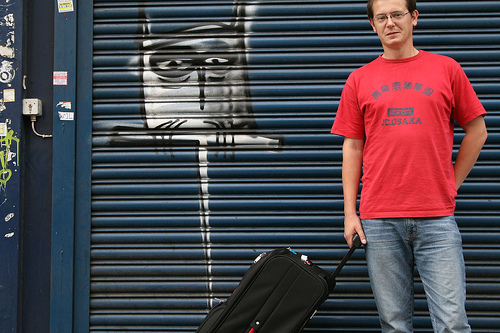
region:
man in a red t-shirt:
[335, 3, 486, 331]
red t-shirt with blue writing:
[330, 53, 484, 211]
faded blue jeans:
[360, 220, 466, 332]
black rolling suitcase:
[180, 233, 362, 330]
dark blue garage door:
[85, 3, 497, 328]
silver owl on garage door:
[112, 5, 281, 318]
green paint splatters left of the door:
[0, 115, 20, 185]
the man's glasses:
[376, 9, 411, 19]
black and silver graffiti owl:
[112, 4, 284, 305]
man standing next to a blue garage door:
[332, 0, 487, 331]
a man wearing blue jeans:
[358, 234, 468, 329]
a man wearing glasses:
[350, 9, 419, 44]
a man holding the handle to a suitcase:
[306, 97, 376, 303]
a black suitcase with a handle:
[226, 220, 368, 330]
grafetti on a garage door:
[113, 6, 288, 166]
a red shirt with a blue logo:
[363, 67, 442, 149]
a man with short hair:
[358, 0, 423, 38]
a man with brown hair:
[349, 2, 441, 39]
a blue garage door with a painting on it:
[106, 19, 347, 239]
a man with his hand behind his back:
[422, 91, 486, 248]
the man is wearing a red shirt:
[333, 46, 483, 216]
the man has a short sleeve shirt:
[330, 48, 485, 216]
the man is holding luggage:
[197, 237, 364, 332]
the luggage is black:
[198, 230, 362, 328]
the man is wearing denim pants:
[358, 220, 475, 330]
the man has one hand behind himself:
[447, 117, 485, 201]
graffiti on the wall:
[116, 4, 273, 311]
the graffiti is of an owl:
[112, 3, 277, 318]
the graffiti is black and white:
[111, 0, 277, 307]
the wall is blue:
[1, 0, 496, 330]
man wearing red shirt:
[346, 5, 496, 329]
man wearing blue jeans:
[350, 5, 488, 328]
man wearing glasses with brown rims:
[363, 1, 437, 53]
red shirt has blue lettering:
[337, 65, 470, 218]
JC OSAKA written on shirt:
[376, 113, 433, 129]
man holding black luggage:
[208, 223, 363, 331]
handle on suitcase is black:
[326, 220, 365, 303]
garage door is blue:
[59, 7, 496, 330]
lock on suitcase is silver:
[296, 250, 316, 274]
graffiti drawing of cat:
[106, 10, 316, 317]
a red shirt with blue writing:
[338, 44, 497, 202]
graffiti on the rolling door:
[101, 9, 298, 195]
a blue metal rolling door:
[88, 4, 498, 331]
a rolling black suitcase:
[162, 223, 375, 331]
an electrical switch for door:
[17, 84, 68, 149]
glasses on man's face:
[368, 1, 413, 25]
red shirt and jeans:
[323, 48, 498, 322]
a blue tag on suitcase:
[283, 240, 298, 256]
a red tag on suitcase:
[245, 325, 257, 331]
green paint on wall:
[0, 126, 26, 202]